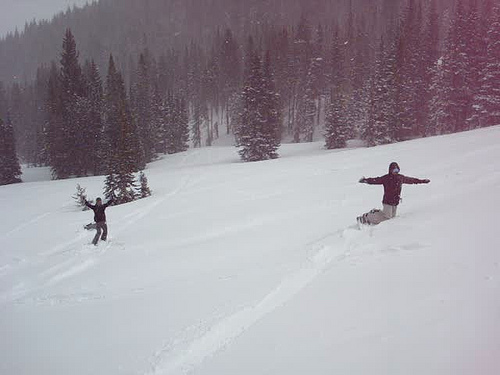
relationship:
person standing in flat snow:
[68, 173, 121, 246] [0, 123, 500, 374]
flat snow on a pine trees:
[0, 123, 500, 374] [226, 31, 283, 161]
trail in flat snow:
[165, 144, 343, 363] [0, 123, 500, 374]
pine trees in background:
[113, 41, 436, 117] [12, 20, 492, 144]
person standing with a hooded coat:
[68, 173, 121, 246] [82, 173, 161, 267]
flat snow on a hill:
[208, 260, 297, 348] [190, 177, 292, 281]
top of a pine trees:
[53, 27, 98, 80] [113, 41, 436, 117]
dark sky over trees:
[8, 3, 48, 28] [12, 20, 492, 144]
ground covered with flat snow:
[165, 144, 343, 363] [0, 123, 500, 374]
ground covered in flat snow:
[165, 144, 343, 363] [0, 123, 500, 374]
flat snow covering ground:
[0, 123, 500, 374] [165, 144, 343, 363]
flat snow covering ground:
[0, 123, 500, 374] [191, 127, 305, 332]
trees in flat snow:
[89, 83, 380, 154] [0, 123, 500, 374]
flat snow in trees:
[0, 123, 500, 374] [89, 83, 380, 154]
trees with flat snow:
[89, 83, 380, 154] [0, 123, 500, 374]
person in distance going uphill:
[57, 135, 155, 247] [64, 112, 184, 331]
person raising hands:
[353, 162, 428, 226] [66, 189, 132, 238]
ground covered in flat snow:
[191, 127, 305, 332] [0, 123, 500, 374]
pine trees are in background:
[113, 41, 436, 117] [12, 20, 492, 144]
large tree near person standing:
[81, 51, 159, 266] [68, 173, 121, 246]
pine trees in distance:
[113, 41, 436, 117] [45, 27, 309, 171]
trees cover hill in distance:
[89, 83, 380, 154] [45, 27, 309, 171]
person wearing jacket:
[353, 162, 428, 226] [376, 157, 406, 212]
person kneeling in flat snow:
[353, 162, 428, 226] [0, 123, 500, 374]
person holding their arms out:
[353, 162, 428, 226] [360, 151, 451, 227]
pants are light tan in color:
[366, 200, 397, 233] [359, 198, 401, 242]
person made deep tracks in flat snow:
[302, 206, 386, 283] [0, 123, 500, 374]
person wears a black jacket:
[360, 151, 451, 227] [359, 114, 432, 226]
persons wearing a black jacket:
[57, 135, 155, 247] [359, 114, 432, 226]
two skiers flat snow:
[52, 128, 497, 240] [0, 123, 500, 374]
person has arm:
[358, 162, 428, 224] [357, 173, 386, 184]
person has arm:
[358, 162, 428, 224] [402, 175, 431, 185]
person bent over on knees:
[353, 162, 428, 226] [380, 209, 398, 223]